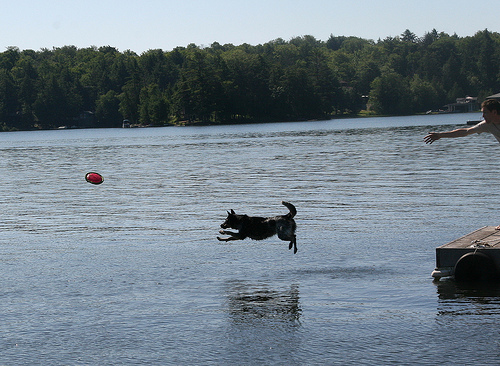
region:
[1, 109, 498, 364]
A lake.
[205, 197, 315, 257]
A dog jumping into the lake.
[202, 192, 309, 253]
The dog is jumping into the water.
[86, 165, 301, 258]
The dog is chasing a ball.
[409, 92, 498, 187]
A person throws a toy in front of the dog.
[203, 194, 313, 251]
The dog is black.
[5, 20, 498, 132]
A line of trees along the water.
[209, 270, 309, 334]
The dog is reflected in the water.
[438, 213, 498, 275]
A wooden float in the water.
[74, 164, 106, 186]
A red toy in the air.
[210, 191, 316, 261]
dog jumps into water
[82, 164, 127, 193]
red disc is flying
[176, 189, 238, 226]
dog has black ears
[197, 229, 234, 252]
dog has black legs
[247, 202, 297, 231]
dog has black body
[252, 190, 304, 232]
dog has black tail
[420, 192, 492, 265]
brown dock with person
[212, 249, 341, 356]
water is light blue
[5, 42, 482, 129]
green trees in distance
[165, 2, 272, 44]
blue and white sky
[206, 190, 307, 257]
black dog jumping into water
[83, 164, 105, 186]
red frisbee hanging mid air over lake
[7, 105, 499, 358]
large blue lake in sunshine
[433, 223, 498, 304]
wooden pier with man standing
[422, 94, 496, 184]
man with arm outstretched over lake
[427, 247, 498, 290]
buoy hanging from white rope off of pier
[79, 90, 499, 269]
man reaching for dog who has jumped into water to retrieve frisbee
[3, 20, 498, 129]
lush green trees lining the background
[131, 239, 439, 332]
reflection of black dog over water in light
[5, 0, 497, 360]
outdoor sunny lake scene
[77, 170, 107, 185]
The dog is going after a ball.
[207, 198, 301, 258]
The dog is jumping.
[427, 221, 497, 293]
There is a wooden deck.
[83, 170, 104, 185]
The ball is red.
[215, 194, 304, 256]
The dog is black.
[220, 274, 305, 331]
The dog's shadow is in the water.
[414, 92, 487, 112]
There are houses in the background.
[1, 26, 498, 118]
There are trees in the background.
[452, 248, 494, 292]
There is an object on the side of the deck.